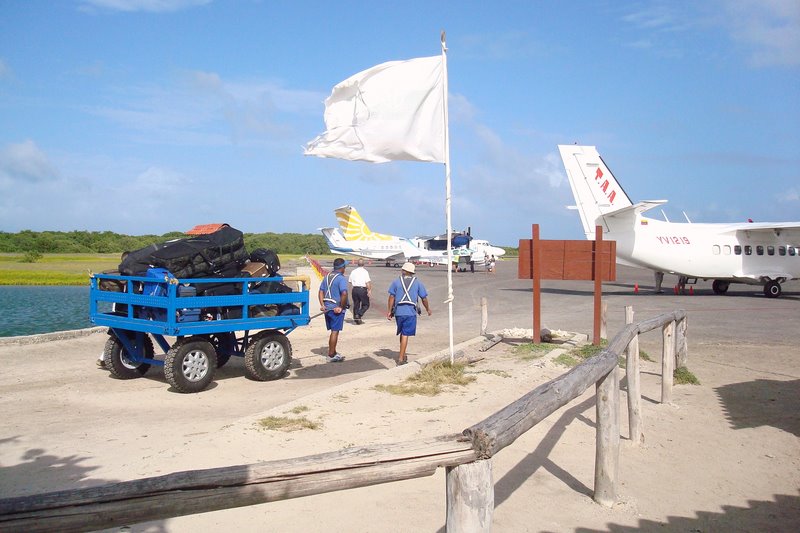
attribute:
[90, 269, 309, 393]
cart — large, blue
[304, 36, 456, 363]
flag — white, here, blowing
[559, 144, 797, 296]
plane — white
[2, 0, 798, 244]
sky — blue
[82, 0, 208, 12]
cloud — white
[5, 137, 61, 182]
cloud — white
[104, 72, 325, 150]
cloud — white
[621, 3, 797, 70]
cloud — white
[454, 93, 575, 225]
cloud — white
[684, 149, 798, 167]
cloud — pale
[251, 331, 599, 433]
sand — here, light brown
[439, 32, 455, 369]
pole — here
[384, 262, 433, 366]
man — standing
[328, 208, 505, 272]
plane — white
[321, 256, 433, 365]
men — walking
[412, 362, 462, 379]
patch of grass — small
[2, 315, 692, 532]
fence — wooden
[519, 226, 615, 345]
sign — brown, large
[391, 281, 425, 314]
shirt — blue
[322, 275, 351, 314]
shirt — blue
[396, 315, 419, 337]
shorts — blue